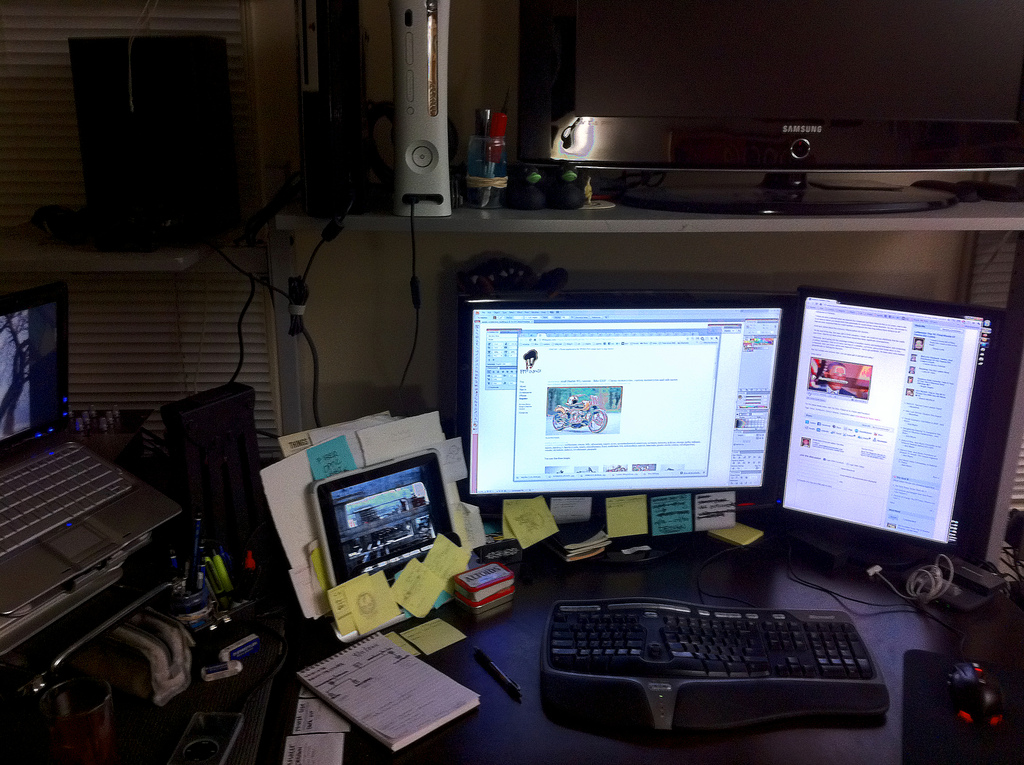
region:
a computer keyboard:
[526, 587, 901, 750]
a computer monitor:
[449, 276, 803, 508]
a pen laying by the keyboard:
[456, 634, 537, 714]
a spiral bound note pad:
[288, 621, 488, 761]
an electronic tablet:
[301, 440, 461, 593]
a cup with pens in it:
[150, 504, 226, 641]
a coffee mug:
[29, 662, 140, 761]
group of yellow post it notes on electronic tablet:
[315, 529, 481, 662]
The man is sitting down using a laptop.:
[403, 481, 590, 672]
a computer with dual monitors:
[462, 287, 976, 600]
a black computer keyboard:
[531, 581, 906, 749]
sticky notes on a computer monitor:
[458, 458, 797, 591]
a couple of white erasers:
[202, 620, 266, 697]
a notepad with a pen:
[281, 623, 525, 750]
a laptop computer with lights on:
[0, 288, 184, 656]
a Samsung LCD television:
[508, 0, 1021, 247]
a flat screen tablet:
[311, 456, 457, 583]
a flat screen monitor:
[796, 262, 997, 558]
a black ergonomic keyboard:
[539, 586, 888, 739]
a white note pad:
[279, 630, 494, 757]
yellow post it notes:
[322, 553, 402, 643]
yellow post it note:
[387, 548, 449, 624]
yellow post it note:
[426, 526, 483, 587]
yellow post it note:
[489, 468, 573, 577]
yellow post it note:
[603, 472, 651, 540]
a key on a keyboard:
[548, 639, 568, 672]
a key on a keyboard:
[576, 645, 593, 661]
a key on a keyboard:
[596, 636, 613, 660]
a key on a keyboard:
[623, 634, 634, 658]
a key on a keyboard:
[639, 645, 658, 662]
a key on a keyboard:
[662, 648, 685, 662]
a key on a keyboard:
[694, 648, 711, 664]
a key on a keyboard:
[721, 637, 729, 645]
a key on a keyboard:
[731, 646, 741, 662]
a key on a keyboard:
[747, 646, 768, 665]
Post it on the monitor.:
[310, 572, 494, 633]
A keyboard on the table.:
[517, 575, 898, 744]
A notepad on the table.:
[302, 639, 486, 738]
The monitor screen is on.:
[477, 313, 782, 490]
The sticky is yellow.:
[347, 578, 420, 621]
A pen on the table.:
[482, 663, 522, 727]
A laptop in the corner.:
[24, 301, 168, 552]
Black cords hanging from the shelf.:
[198, 227, 339, 354]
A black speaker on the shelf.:
[49, 26, 250, 238]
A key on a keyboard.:
[601, 627, 620, 641]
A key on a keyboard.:
[699, 639, 709, 649]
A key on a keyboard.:
[724, 627, 740, 644]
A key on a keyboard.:
[778, 617, 792, 630]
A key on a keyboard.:
[558, 615, 584, 635]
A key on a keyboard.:
[584, 624, 601, 641]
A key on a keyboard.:
[607, 630, 626, 646]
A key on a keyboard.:
[580, 640, 591, 654]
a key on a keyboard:
[568, 607, 581, 617]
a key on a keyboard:
[592, 608, 609, 621]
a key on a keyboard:
[554, 624, 564, 638]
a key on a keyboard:
[579, 633, 598, 638]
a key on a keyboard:
[549, 637, 565, 657]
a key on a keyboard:
[613, 640, 629, 654]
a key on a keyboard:
[698, 646, 709, 660]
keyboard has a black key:
[599, 613, 610, 624]